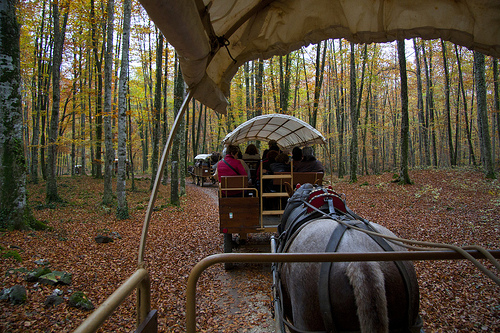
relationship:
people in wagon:
[224, 140, 328, 178] [202, 106, 335, 278]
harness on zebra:
[277, 193, 359, 239] [273, 179, 420, 333]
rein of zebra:
[315, 205, 424, 252] [273, 179, 420, 333]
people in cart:
[224, 140, 328, 178] [207, 101, 348, 282]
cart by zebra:
[207, 101, 348, 282] [273, 179, 420, 333]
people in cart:
[224, 140, 328, 178] [218, 113, 329, 273]